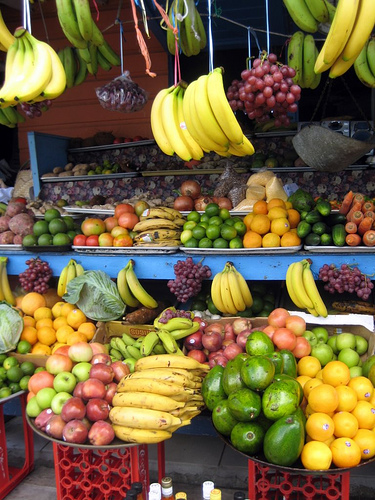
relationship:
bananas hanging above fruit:
[156, 62, 257, 161] [1, 197, 370, 475]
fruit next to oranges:
[179, 198, 244, 247] [237, 197, 305, 258]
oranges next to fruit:
[237, 197, 305, 258] [179, 198, 244, 247]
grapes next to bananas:
[166, 254, 213, 306] [208, 259, 255, 315]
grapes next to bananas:
[12, 254, 60, 302] [55, 259, 89, 301]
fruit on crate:
[24, 343, 215, 451] [47, 431, 171, 497]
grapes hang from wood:
[166, 254, 213, 306] [5, 252, 374, 284]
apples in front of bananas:
[187, 314, 257, 362] [208, 259, 255, 315]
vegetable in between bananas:
[66, 270, 130, 326] [55, 259, 89, 301]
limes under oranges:
[1, 353, 42, 405] [19, 293, 104, 365]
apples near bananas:
[187, 314, 257, 362] [208, 259, 255, 315]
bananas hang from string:
[156, 62, 257, 161] [156, 11, 194, 88]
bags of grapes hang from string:
[96, 72, 147, 113] [105, 17, 137, 77]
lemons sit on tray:
[242, 169, 292, 210] [230, 192, 291, 214]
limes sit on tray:
[185, 205, 251, 248] [176, 243, 307, 257]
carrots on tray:
[344, 191, 374, 245] [303, 239, 375, 256]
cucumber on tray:
[301, 197, 346, 245] [303, 239, 375, 256]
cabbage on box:
[66, 270, 130, 326] [88, 320, 165, 342]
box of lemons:
[88, 320, 165, 342] [12, 299, 100, 360]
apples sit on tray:
[26, 344, 120, 443] [21, 427, 172, 454]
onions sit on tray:
[261, 306, 308, 357] [208, 422, 374, 480]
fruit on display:
[1, 197, 370, 475] [1, 178, 374, 457]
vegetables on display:
[3, 189, 372, 249] [1, 178, 374, 457]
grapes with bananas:
[166, 254, 213, 306] [208, 259, 255, 315]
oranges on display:
[237, 197, 305, 258] [1, 178, 374, 457]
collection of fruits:
[1, 178, 374, 457] [1, 197, 370, 475]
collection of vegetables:
[1, 178, 374, 457] [3, 189, 372, 249]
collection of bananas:
[3, 16, 371, 178] [156, 62, 257, 161]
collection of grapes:
[3, 16, 371, 178] [166, 254, 213, 306]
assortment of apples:
[27, 342, 128, 450] [26, 344, 120, 443]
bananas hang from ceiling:
[156, 62, 257, 161] [1, 1, 372, 73]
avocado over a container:
[25, 202, 82, 252] [21, 244, 74, 254]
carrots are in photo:
[344, 191, 374, 245] [1, 1, 374, 498]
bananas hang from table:
[208, 259, 255, 315] [5, 252, 374, 284]